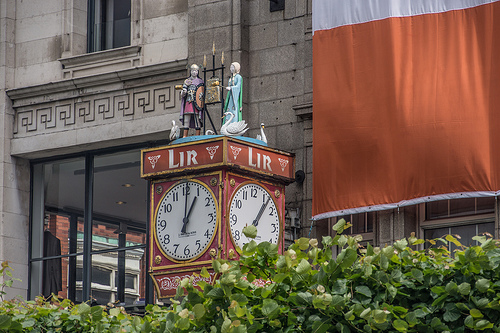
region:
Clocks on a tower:
[133, 168, 309, 286]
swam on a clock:
[219, 105, 248, 141]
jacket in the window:
[33, 223, 73, 310]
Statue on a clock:
[176, 55, 247, 135]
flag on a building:
[295, 5, 492, 200]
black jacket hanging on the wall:
[35, 223, 72, 302]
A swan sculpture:
[214, 107, 251, 137]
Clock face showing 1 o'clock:
[151, 172, 220, 266]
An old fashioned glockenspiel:
[134, 37, 299, 294]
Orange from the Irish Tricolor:
[301, 0, 496, 227]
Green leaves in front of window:
[295, 222, 495, 332]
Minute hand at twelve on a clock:
[177, 175, 190, 236]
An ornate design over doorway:
[12, 90, 137, 181]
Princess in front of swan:
[217, 57, 251, 135]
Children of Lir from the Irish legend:
[133, 52, 299, 178]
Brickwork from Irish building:
[250, 34, 308, 99]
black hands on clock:
[171, 182, 207, 229]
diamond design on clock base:
[196, 138, 227, 158]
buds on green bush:
[236, 271, 287, 288]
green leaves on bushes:
[355, 240, 430, 292]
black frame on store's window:
[31, 154, 119, 286]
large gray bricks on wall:
[246, 23, 290, 65]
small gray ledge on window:
[38, 43, 175, 61]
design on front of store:
[19, 92, 190, 124]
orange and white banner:
[291, 4, 492, 243]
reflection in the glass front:
[53, 225, 160, 319]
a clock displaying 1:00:
[154, 180, 219, 263]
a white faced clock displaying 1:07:
[224, 181, 281, 261]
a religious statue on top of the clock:
[169, 41, 254, 135]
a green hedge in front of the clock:
[0, 263, 498, 332]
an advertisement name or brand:
[143, 141, 220, 168]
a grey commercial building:
[0, 0, 173, 131]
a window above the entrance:
[63, 1, 141, 65]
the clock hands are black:
[181, 183, 197, 237]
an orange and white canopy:
[312, 0, 499, 218]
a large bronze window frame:
[23, 145, 145, 312]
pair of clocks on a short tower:
[142, 142, 294, 293]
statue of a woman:
[224, 59, 244, 134]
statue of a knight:
[179, 62, 206, 139]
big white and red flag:
[314, 0, 498, 222]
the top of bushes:
[240, 237, 492, 329]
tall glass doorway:
[29, 143, 170, 315]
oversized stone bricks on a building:
[256, 39, 304, 114]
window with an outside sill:
[59, 0, 145, 80]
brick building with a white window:
[48, 208, 142, 299]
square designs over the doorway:
[13, 79, 207, 130]